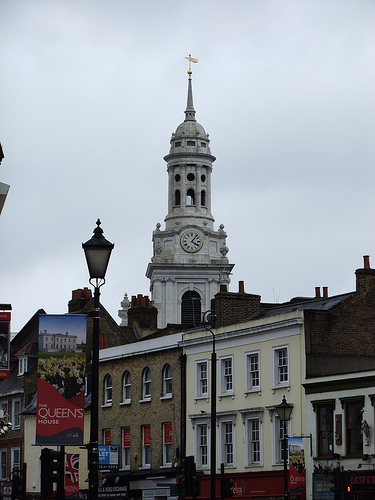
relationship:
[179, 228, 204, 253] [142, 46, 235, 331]
clock on clock tower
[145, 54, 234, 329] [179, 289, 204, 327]
clock tower on archway window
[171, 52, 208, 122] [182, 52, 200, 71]
steeple on weather vane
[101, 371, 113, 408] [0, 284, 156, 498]
curved window on building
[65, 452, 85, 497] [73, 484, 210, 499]
flag on road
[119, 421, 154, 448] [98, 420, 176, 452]
white shades on windows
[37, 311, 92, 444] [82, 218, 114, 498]
advertising banner on lamp post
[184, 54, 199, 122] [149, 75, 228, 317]
steeple on clock tower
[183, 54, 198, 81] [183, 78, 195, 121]
weather vane on steeple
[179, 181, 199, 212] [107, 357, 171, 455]
window in building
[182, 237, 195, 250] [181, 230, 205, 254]
numerals on clock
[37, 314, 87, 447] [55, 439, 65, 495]
sign on pole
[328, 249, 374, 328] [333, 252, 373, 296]
roof on chimney